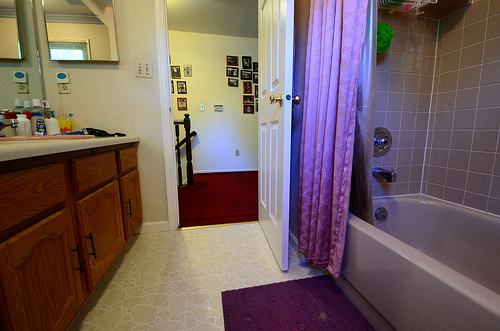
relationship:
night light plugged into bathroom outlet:
[52, 67, 69, 86] [52, 66, 70, 94]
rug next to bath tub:
[221, 271, 389, 330] [330, 178, 500, 331]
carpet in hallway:
[177, 169, 262, 230] [168, 0, 258, 229]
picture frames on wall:
[220, 51, 259, 117] [168, 29, 256, 174]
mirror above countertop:
[38, 0, 120, 69] [2, 134, 142, 167]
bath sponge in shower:
[369, 21, 395, 62] [301, 9, 484, 327]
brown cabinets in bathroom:
[0, 145, 143, 323] [6, 2, 481, 318]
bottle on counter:
[21, 90, 46, 133] [0, 92, 144, 157]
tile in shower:
[365, 0, 500, 216] [315, 15, 481, 313]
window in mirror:
[16, 41, 91, 61] [0, 0, 120, 62]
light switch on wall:
[133, 59, 156, 80] [110, 2, 170, 222]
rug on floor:
[221, 281, 384, 329] [61, 216, 347, 329]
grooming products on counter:
[5, 93, 88, 140] [5, 84, 143, 149]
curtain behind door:
[294, 0, 364, 281] [246, 1, 302, 271]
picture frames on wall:
[225, 54, 259, 115] [174, 28, 264, 180]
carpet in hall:
[179, 162, 269, 230] [158, 4, 268, 224]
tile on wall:
[399, 35, 461, 155] [375, 14, 484, 198]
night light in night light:
[56, 71, 70, 84] [56, 71, 70, 84]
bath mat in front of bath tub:
[218, 257, 348, 327] [330, 178, 483, 315]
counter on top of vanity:
[2, 96, 150, 155] [10, 147, 143, 323]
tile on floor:
[101, 183, 289, 319] [56, 163, 345, 326]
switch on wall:
[132, 56, 160, 82] [94, 81, 139, 116]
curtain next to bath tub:
[294, 0, 364, 281] [330, 178, 500, 331]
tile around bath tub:
[365, 0, 500, 216] [330, 178, 500, 331]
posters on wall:
[221, 52, 244, 98] [201, 130, 231, 168]